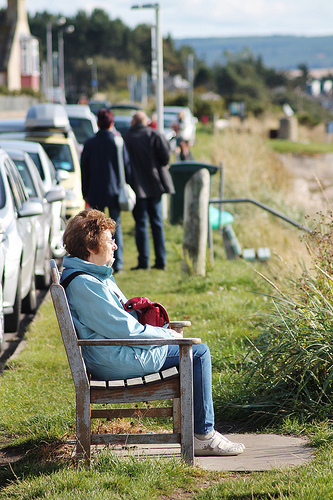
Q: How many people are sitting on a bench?
A: One.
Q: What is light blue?
A: Woman's jacket.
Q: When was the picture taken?
A: Daytime.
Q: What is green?
A: Grass.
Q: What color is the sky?
A: Blue.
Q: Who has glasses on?
A: A woman.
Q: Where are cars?
A: Parked on side of road.